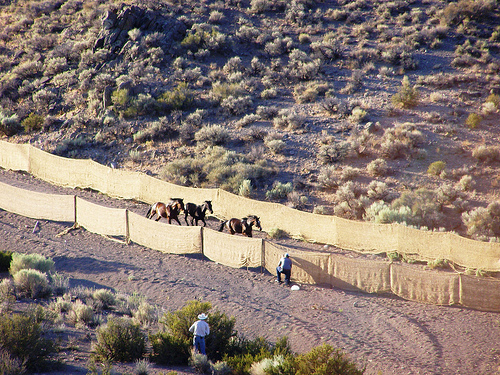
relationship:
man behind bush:
[186, 312, 210, 354] [166, 298, 233, 367]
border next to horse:
[1, 181, 499, 314] [220, 213, 263, 239]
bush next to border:
[156, 158, 213, 187] [0, 136, 499, 272]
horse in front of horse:
[220, 213, 263, 239] [183, 199, 216, 227]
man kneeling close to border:
[274, 253, 292, 286] [1, 181, 499, 314]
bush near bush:
[166, 298, 233, 367] [145, 328, 193, 369]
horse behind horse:
[142, 198, 187, 225] [183, 199, 216, 227]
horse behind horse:
[183, 199, 216, 227] [220, 213, 263, 239]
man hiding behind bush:
[186, 312, 210, 354] [166, 298, 233, 367]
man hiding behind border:
[274, 253, 295, 289] [1, 181, 499, 314]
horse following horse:
[183, 199, 216, 227] [220, 213, 263, 239]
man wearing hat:
[186, 312, 210, 359] [195, 312, 209, 321]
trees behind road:
[0, 2, 498, 245] [1, 167, 499, 281]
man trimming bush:
[186, 312, 210, 359] [148, 329, 191, 367]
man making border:
[274, 253, 295, 289] [1, 181, 499, 314]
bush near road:
[148, 329, 191, 367] [1, 167, 499, 281]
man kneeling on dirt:
[274, 253, 295, 289] [1, 212, 497, 375]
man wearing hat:
[186, 312, 210, 354] [195, 312, 209, 321]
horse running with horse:
[220, 213, 263, 239] [183, 199, 216, 227]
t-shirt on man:
[276, 254, 292, 273] [274, 253, 295, 289]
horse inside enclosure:
[220, 213, 263, 239] [2, 136, 499, 316]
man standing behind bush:
[186, 312, 210, 359] [166, 298, 233, 367]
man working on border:
[274, 253, 295, 289] [1, 181, 499, 314]